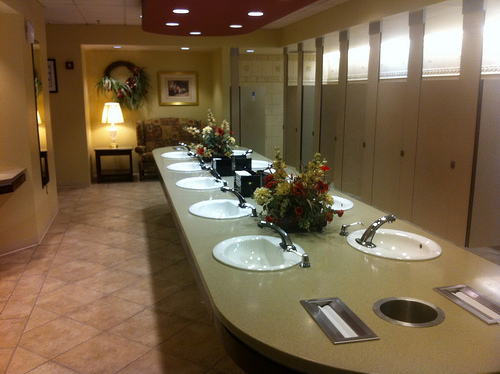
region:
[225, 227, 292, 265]
this is a sink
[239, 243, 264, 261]
the sink is white in color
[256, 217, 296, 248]
this is the tap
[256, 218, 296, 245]
the tap is metallic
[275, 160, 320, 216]
this is a flower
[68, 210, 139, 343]
this is the floor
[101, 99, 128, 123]
this is a lump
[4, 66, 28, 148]
this is the wall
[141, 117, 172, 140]
this is a couch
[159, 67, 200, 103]
this is a picture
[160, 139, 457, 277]
Public bathroom sinks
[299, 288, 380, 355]
Hand towels for drying hands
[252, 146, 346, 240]
Beautiful flower arrangements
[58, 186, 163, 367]
Tile flooring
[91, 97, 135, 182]
lamp on top of a table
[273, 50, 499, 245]
Public bathroom stalls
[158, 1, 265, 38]
Lights on the ceiling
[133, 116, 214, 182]
Comfy chair to sit on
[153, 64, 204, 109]
Photo frame on the wall for decor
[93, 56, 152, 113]
Wreath on the wall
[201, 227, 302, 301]
The sink is white.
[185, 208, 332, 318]
The sink is white.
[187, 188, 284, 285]
The sink is white.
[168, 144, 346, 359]
The sink is white.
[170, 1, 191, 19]
light on a red ceiling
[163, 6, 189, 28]
two lights on a red ceiling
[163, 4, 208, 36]
three lights on a red ceiling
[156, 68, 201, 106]
art on the wall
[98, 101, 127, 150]
brightly lit lamp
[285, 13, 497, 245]
row of tan bathroom stalls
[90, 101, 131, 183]
brightly lit lamp on a wooden table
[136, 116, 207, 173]
floral pattern sofa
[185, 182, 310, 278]
two white sinks with silver faucets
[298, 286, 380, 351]
silver paper dispenser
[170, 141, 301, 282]
row of white sinks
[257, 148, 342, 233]
flowers on bathroom counter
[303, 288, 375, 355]
towel dispenser in counter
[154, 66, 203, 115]
picture with gold frame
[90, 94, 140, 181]
lit lamp on table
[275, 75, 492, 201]
refelction of bathroom stalls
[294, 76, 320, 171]
open door of stall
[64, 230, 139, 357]
tiles on bathroom floor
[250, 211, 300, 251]
curved faucet over sink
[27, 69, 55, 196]
mirror on bathroom wall